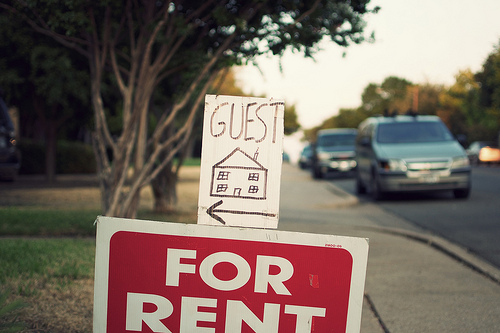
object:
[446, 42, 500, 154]
trees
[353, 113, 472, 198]
car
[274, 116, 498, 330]
street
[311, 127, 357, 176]
car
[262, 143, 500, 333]
sidewalk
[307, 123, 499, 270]
road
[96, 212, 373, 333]
rent sign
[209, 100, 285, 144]
word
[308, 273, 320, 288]
scar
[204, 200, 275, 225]
arrow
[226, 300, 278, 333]
letter n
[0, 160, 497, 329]
ground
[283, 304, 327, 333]
letter t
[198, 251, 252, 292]
letter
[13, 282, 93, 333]
dried grass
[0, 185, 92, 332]
lawn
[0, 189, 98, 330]
grasslands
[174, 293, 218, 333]
letter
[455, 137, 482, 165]
car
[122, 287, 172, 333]
letter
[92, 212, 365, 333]
book bag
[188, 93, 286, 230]
paper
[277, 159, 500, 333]
curb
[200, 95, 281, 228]
drawing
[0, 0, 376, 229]
tree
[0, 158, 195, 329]
yard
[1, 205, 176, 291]
grass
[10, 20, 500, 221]
background